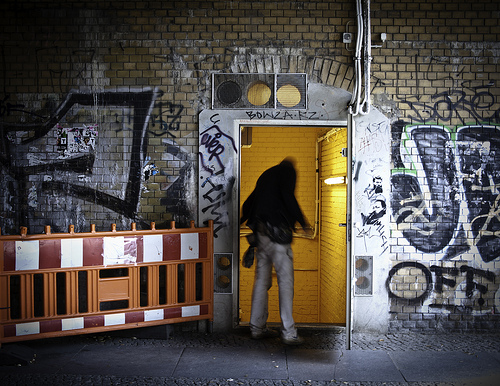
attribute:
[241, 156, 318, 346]
person — walking, down, standin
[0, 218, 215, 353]
gate — plastic, protective, orange, checkered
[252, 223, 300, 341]
pants — white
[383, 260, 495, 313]
graffiti — black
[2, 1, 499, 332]
wall — tagged, bright, brick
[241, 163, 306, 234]
jacket — black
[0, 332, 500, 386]
sidewalk — pavement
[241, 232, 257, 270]
bag — plastic